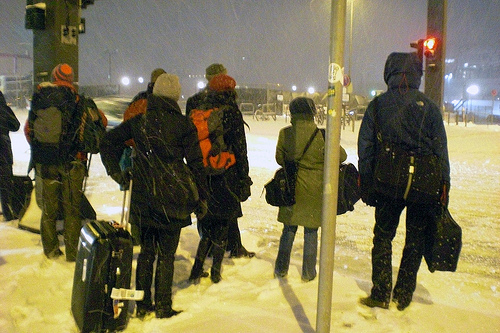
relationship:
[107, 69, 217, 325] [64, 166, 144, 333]
woman has suitcase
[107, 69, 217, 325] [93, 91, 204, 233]
woman wearing coat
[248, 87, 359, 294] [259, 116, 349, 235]
woman wearing coat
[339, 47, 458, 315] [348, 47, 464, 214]
man wearing coat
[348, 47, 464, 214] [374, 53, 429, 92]
coat has hood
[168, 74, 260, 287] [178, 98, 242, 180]
woman carrying backpack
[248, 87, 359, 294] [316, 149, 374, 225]
woman carrying backpack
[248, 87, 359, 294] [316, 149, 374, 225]
woman has backpack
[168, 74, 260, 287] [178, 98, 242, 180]
woman has backpack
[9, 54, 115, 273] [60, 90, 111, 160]
man has backpack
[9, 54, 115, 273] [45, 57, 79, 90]
man has cap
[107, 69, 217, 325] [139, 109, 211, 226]
woman has handbag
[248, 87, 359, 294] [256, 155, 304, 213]
woman has handbag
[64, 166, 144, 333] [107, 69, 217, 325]
suitcase behind woman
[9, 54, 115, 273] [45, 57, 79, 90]
man wearing cap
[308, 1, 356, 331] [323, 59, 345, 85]
pole has sticker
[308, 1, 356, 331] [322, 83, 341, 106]
pole has sticker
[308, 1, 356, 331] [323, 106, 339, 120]
pole has sticker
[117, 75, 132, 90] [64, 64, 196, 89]
light on background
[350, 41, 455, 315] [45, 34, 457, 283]
man has jackets